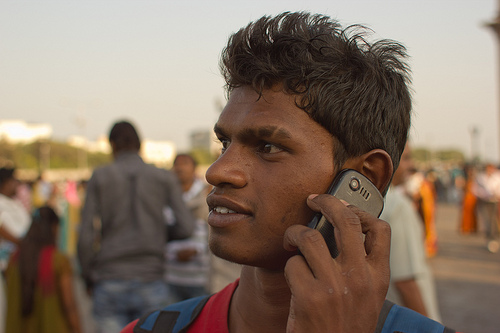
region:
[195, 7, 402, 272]
man with cellphone to his ear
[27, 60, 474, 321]
man outdoors near other people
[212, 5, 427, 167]
hair standing up and curled away from face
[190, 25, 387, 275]
face looking to side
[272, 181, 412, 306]
fingers curled around cellphone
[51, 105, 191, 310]
man in grey shirt with back turned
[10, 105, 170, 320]
short female next to tall man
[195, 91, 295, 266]
man relaxed with lips parted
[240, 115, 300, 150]
slant of skin across eyebrow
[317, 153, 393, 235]
button and three vents on cellphone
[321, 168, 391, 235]
this is a mobile phone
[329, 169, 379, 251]
the phone is black in color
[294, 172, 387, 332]
the man is holding the phone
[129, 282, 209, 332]
the man is carrying a bag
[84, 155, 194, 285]
this man is wearing a shirt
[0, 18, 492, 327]
these are people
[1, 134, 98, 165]
these are trees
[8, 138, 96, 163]
the trees are green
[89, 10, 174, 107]
this is the sky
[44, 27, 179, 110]
the sky is blue in color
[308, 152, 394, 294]
phone is silver and small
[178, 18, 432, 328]
man has black hair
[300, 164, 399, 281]
this is a mobile phone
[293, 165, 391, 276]
the phone is black in color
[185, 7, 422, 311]
the man is making a call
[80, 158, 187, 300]
the man is wearing a shirt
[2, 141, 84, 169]
these are trees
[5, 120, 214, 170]
these are building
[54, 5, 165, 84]
the sky is blue in color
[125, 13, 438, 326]
the man is looking at something while making a call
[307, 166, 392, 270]
gray phone held to ear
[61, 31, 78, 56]
white clouds in blue sky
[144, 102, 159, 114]
white clouds in blue sky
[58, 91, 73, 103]
white clouds in blue sky